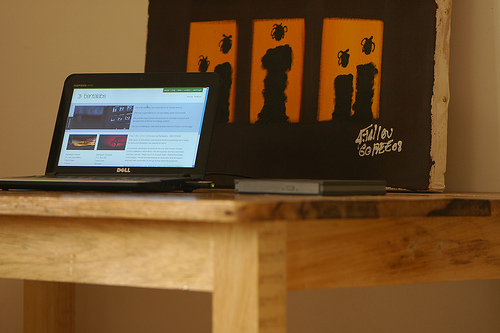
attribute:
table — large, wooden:
[202, 192, 302, 289]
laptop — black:
[1, 72, 222, 191]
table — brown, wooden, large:
[2, 188, 499, 329]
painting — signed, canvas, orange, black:
[140, 2, 444, 192]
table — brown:
[31, 175, 484, 323]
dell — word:
[115, 167, 132, 173]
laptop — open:
[48, 80, 342, 279]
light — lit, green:
[206, 177, 223, 195]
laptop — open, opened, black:
[0, 65, 227, 196]